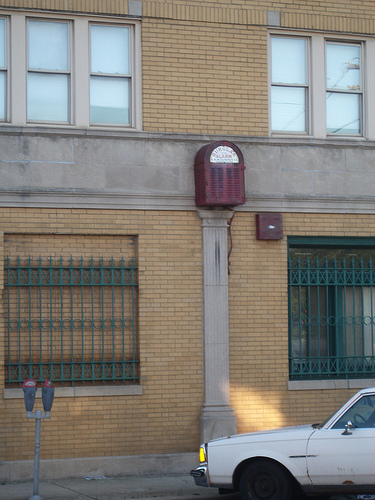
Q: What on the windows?
A: Green iron bars.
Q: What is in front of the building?
A: A white car.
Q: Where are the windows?
A: On the building.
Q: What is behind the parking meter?
A: A building.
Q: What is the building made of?
A: Tan brick.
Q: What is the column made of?
A: Gray stone.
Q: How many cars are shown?
A: One.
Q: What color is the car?
A: White.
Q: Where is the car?
A: The street.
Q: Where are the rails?
A: On windows.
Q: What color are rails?
A: Green.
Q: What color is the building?
A: Tan.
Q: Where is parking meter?
A: Sidewalk.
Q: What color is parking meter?
A: Gray.